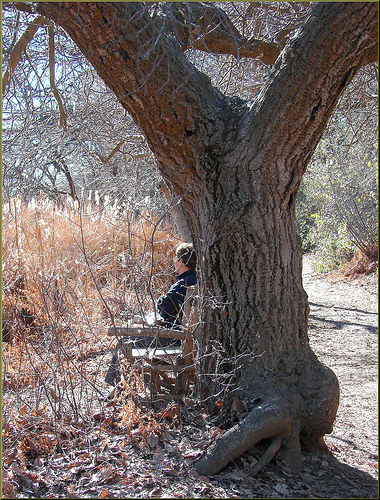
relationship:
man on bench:
[103, 244, 198, 401] [108, 286, 204, 403]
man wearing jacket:
[103, 244, 198, 401] [119, 270, 204, 315]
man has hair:
[103, 244, 198, 401] [172, 240, 199, 271]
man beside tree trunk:
[103, 244, 198, 401] [153, 159, 338, 476]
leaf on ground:
[146, 431, 157, 448] [1, 253, 379, 498]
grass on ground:
[1, 184, 183, 498] [29, 312, 362, 477]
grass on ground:
[323, 249, 374, 289] [313, 229, 378, 363]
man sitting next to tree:
[103, 244, 198, 401] [191, 23, 331, 351]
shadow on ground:
[308, 296, 367, 338] [313, 270, 367, 371]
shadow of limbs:
[308, 296, 367, 338] [184, 23, 378, 169]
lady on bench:
[102, 240, 198, 389] [104, 284, 197, 403]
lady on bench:
[103, 243, 197, 397] [108, 286, 204, 403]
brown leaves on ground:
[3, 363, 276, 499] [23, 212, 358, 482]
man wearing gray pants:
[103, 244, 198, 401] [103, 323, 178, 383]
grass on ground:
[1, 184, 183, 498] [1, 253, 379, 498]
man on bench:
[103, 244, 196, 385] [104, 284, 197, 403]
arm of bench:
[106, 323, 191, 342] [108, 281, 200, 421]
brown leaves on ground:
[3, 363, 276, 499] [43, 420, 157, 485]